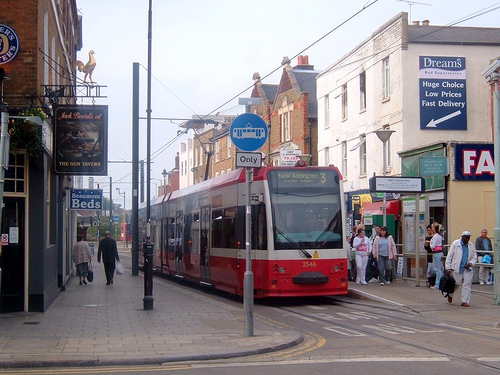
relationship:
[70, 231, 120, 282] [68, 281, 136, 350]
people walking on sidewalk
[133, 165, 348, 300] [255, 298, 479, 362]
bus on street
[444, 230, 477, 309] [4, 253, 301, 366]
man walking in sidewalk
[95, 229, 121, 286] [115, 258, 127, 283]
man holding bag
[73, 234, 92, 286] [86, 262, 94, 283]
people carrying a bag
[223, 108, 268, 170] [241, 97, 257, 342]
sign on top of post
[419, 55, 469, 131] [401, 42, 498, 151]
advertisement on wall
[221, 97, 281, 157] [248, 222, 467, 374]
blue sign on street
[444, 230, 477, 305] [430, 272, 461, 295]
man carrying suitcase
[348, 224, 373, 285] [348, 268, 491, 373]
lady walking on pavement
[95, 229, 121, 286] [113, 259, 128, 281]
man carrying bag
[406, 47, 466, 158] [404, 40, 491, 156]
sign on wall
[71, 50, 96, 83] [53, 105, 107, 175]
statue on sign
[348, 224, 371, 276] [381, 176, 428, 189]
lady wearing white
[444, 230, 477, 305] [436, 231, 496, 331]
man wearing white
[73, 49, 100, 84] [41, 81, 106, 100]
rooster on pole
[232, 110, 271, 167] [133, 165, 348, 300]
sign on bus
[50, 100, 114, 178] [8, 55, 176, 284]
sign on wall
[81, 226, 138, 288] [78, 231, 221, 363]
man on sidewalk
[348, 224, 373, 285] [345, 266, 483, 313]
lady on sidewalk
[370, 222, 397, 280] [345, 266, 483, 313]
woman on sidewalk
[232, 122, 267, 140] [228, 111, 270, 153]
white bus on blue sign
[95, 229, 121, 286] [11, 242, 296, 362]
man on sidewalk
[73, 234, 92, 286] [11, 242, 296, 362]
people on sidewalk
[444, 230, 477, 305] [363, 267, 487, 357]
man walking on pavement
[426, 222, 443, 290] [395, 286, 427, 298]
person walking on pavement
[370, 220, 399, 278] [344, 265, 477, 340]
person walking on pavement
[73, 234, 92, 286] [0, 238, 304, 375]
people walking on pavement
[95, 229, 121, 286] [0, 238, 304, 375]
man walking on pavement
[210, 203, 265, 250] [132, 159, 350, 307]
window on bus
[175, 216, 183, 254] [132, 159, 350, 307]
window on bus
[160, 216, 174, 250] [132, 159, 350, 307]
window on bus